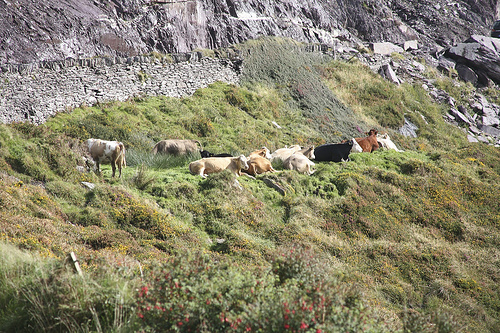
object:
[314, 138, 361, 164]
cows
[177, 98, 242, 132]
bush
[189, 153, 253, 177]
cow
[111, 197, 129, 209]
flowers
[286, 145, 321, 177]
cow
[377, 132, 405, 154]
cow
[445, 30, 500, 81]
rocks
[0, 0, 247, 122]
hillside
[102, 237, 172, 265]
bushes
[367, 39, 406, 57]
rock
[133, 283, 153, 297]
flowers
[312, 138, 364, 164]
cow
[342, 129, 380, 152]
cow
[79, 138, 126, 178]
cow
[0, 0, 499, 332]
hill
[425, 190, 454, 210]
flowers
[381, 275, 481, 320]
bushes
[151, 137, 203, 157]
cow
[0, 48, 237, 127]
wall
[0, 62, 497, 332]
grass